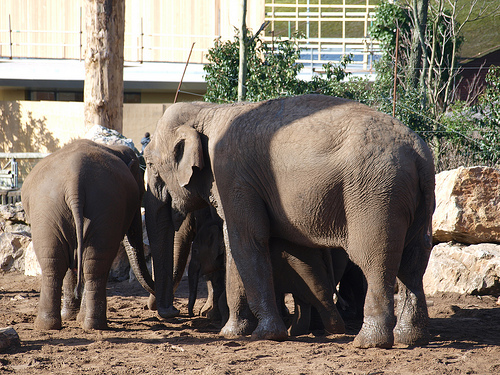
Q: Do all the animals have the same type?
A: Yes, all the animals are elephants.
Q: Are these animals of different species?
A: No, all the animals are elephants.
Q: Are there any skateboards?
A: No, there are no skateboards.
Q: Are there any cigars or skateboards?
A: No, there are no skateboards or cigars.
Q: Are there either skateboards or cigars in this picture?
A: No, there are no skateboards or cigars.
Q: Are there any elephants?
A: Yes, there is an elephant.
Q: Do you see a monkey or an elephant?
A: Yes, there is an elephant.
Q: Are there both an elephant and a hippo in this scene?
A: No, there is an elephant but no hippoes.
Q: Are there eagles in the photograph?
A: No, there are no eagles.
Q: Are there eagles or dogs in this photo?
A: No, there are no eagles or dogs.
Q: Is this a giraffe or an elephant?
A: This is an elephant.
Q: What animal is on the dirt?
A: The elephant is on the dirt.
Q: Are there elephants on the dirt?
A: Yes, there is an elephant on the dirt.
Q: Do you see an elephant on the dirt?
A: Yes, there is an elephant on the dirt.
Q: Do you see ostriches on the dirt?
A: No, there is an elephant on the dirt.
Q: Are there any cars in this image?
A: No, there are no cars.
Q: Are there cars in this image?
A: No, there are no cars.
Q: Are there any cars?
A: No, there are no cars.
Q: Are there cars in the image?
A: No, there are no cars.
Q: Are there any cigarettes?
A: No, there are no cigarettes.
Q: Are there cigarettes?
A: No, there are no cigarettes.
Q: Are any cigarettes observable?
A: No, there are no cigarettes.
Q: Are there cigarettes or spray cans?
A: No, there are no cigarettes or spray cans.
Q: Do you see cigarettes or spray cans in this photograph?
A: No, there are no cigarettes or spray cans.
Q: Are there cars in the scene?
A: No, there are no cars.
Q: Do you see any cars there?
A: No, there are no cars.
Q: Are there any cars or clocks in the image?
A: No, there are no cars or clocks.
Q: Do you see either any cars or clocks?
A: No, there are no cars or clocks.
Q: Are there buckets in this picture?
A: No, there are no buckets.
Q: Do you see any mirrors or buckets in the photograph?
A: No, there are no buckets or mirrors.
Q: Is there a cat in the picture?
A: No, there are no cats.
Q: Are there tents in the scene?
A: No, there are no tents.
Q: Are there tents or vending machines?
A: No, there are no tents or vending machines.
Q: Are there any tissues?
A: No, there are no tissues.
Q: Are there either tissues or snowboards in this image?
A: No, there are no tissues or snowboards.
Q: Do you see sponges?
A: No, there are no sponges.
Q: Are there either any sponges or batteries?
A: No, there are no sponges or batteries.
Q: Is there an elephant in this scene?
A: Yes, there is an elephant.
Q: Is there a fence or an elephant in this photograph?
A: Yes, there is an elephant.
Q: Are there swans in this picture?
A: No, there are no swans.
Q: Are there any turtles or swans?
A: No, there are no swans or turtles.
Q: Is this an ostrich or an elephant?
A: This is an elephant.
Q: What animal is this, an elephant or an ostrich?
A: This is an elephant.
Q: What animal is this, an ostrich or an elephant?
A: This is an elephant.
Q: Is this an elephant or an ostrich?
A: This is an elephant.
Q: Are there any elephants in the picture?
A: Yes, there is an elephant.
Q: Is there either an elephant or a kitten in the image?
A: Yes, there is an elephant.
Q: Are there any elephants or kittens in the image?
A: Yes, there is an elephant.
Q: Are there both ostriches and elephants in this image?
A: No, there is an elephant but no ostriches.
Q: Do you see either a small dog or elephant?
A: Yes, there is a small elephant.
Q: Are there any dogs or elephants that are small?
A: Yes, the elephant is small.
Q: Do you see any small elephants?
A: Yes, there is a small elephant.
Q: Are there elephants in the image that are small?
A: Yes, there is an elephant that is small.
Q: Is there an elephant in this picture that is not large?
A: Yes, there is a small elephant.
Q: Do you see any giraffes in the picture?
A: No, there are no giraffes.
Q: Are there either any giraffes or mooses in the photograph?
A: No, there are no giraffes or mooses.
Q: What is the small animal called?
A: The animal is an elephant.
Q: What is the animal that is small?
A: The animal is an elephant.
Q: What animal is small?
A: The animal is an elephant.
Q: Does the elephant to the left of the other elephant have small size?
A: Yes, the elephant is small.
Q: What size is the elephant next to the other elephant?
A: The elephant is small.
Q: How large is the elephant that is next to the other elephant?
A: The elephant is small.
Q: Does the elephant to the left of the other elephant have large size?
A: No, the elephant is small.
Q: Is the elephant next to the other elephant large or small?
A: The elephant is small.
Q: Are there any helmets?
A: No, there are no helmets.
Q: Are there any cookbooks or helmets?
A: No, there are no helmets or cookbooks.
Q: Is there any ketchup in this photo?
A: Yes, there is ketchup.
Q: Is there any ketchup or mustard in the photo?
A: Yes, there is ketchup.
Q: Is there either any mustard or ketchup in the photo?
A: Yes, there is ketchup.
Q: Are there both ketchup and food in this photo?
A: No, there is ketchup but no food.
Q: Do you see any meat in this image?
A: No, there is no meat.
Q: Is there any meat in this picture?
A: No, there is no meat.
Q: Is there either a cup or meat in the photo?
A: No, there are no meat or cups.